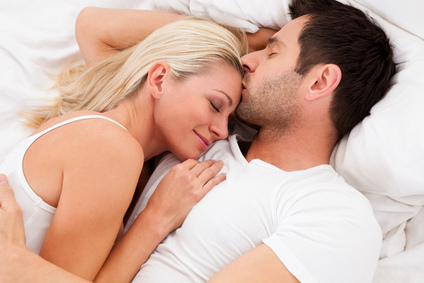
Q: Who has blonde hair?
A: A woman.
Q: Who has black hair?
A: A man.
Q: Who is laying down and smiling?
A: A woman.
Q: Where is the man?
A: Lying down in bed with a woman.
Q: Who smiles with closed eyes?
A: A woman.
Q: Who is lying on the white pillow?
A: A man.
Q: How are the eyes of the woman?
A: Closed.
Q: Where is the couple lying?
A: In bed.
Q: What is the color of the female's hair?
A: Blonde.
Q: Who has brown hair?
A: A man.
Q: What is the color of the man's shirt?
A: White.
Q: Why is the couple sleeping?
A: To rest.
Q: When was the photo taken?
A: Night.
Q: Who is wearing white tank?
A: Blonde.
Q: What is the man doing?
A: Kissing.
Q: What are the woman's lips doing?
A: Smiling.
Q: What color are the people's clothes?
A: White.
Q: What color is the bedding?
A: White.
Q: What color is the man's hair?
A: Brown.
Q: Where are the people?
A: In bed.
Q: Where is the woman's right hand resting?
A: Man's chest.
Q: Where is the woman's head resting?
A: Man's arm.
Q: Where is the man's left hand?
A: Woman's back.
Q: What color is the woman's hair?
A: Blonde.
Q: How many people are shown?
A: 2.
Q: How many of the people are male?
A: 1.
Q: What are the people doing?
A: Laying.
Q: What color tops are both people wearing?
A: White.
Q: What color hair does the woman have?
A: Blond.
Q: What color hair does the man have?
A: Black.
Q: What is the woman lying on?
A: Man's arm.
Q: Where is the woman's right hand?
A: Man's chest.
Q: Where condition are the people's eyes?
A: Closed.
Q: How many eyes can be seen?
A: 2.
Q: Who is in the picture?
A: A man and woman.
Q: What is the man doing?
A: Kissing the woman.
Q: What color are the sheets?
A: White.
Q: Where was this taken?
A: In the bedroom.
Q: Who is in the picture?
A: A man and a woman.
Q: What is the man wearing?
A: A tee shirt.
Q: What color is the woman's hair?
A: Blonde.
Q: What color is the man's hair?
A: Black.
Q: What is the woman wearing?
A: A tank top.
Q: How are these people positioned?
A: They are laying down.